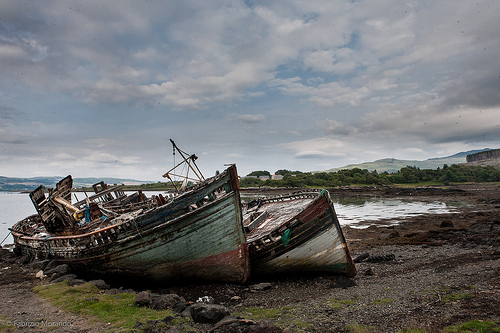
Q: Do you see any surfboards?
A: No, there are no surfboards.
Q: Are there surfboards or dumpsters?
A: No, there are no surfboards or dumpsters.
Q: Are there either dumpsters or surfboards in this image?
A: No, there are no surfboards or dumpsters.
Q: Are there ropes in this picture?
A: No, there are no ropes.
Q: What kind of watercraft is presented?
A: The watercraft is boats.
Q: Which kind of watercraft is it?
A: The watercraft is boats.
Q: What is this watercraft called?
A: These are boats.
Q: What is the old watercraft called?
A: The watercraft is boats.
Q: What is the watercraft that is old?
A: The watercraft is boats.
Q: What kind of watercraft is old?
A: The watercraft is boats.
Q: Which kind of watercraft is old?
A: The watercraft is boats.